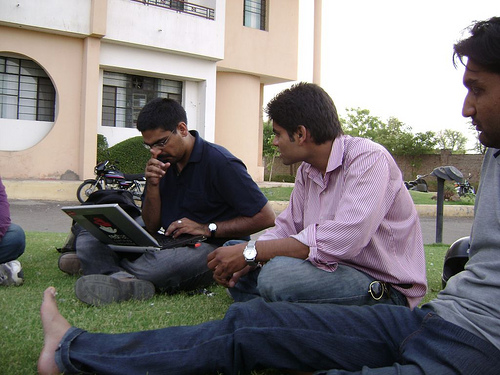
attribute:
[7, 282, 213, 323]
grass — green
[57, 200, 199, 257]
laptop — black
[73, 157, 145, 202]
motor bike — purple, red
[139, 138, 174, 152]
sunglasses — silver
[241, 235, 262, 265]
watch — silver, balck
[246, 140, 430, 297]
shirt — pink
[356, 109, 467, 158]
leaves — green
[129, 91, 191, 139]
hair — short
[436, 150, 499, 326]
shirt — gray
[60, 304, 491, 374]
pants — blue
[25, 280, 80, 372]
foot — bare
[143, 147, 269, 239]
shirt — dark blue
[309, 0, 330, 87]
pole — metal